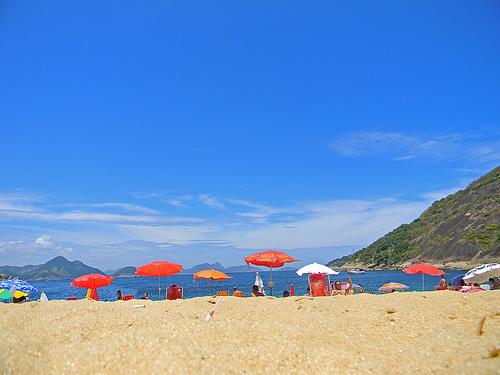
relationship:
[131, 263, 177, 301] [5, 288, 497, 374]
umbrella on beach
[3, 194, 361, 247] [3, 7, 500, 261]
clouds in sky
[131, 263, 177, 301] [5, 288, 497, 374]
umbrella in sand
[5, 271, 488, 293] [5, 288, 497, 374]
people on beach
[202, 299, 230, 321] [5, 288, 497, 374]
cigarette on beach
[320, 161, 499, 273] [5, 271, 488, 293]
mountain going into ocean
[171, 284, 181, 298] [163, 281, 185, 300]
person on chair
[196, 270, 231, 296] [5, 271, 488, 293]
umbrella facing water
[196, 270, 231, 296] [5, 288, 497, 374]
umbrella in sand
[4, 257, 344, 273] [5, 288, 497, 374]
mountains by beach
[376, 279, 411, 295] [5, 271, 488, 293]
umbrella near water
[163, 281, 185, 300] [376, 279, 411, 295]
chair under umbrella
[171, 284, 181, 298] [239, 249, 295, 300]
person under umbrella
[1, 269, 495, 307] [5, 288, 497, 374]
water by beach